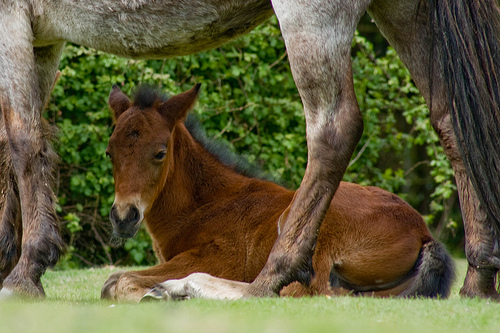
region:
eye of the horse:
[150, 145, 165, 160]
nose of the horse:
[110, 200, 146, 236]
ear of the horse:
[167, 90, 202, 121]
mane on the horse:
[187, 118, 245, 173]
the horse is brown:
[367, 223, 395, 256]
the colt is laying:
[82, 102, 426, 294]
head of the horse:
[93, 83, 182, 233]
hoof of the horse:
[242, 272, 305, 295]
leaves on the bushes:
[222, 85, 287, 132]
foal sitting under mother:
[81, 59, 446, 314]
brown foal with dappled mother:
[2, 0, 498, 332]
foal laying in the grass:
[66, 64, 463, 324]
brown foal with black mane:
[91, 75, 461, 319]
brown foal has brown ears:
[81, 70, 461, 327]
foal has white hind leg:
[134, 263, 268, 316]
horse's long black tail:
[419, 2, 496, 208]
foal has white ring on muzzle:
[98, 180, 153, 239]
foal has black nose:
[105, 200, 150, 242]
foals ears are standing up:
[99, 82, 213, 124]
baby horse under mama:
[73, 70, 444, 305]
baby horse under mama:
[37, 75, 459, 318]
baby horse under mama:
[76, 70, 453, 309]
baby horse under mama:
[10, 74, 442, 314]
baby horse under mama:
[97, 60, 460, 306]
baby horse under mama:
[57, 39, 456, 309]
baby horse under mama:
[33, 66, 450, 321]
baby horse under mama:
[72, 30, 460, 315]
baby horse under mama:
[64, 74, 460, 318]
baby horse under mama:
[10, 54, 455, 314]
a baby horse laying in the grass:
[100, 81, 455, 302]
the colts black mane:
[130, 82, 162, 112]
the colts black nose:
[109, 204, 141, 241]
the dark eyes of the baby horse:
[152, 145, 162, 160]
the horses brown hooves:
[1, 267, 46, 304]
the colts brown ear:
[157, 82, 201, 129]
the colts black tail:
[403, 240, 455, 302]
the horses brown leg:
[246, 0, 364, 295]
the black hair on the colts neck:
[188, 112, 258, 179]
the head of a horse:
[87, 82, 225, 244]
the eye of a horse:
[142, 142, 182, 171]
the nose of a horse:
[109, 196, 156, 238]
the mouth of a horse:
[103, 180, 176, 251]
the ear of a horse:
[142, 78, 221, 140]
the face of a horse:
[100, 99, 202, 234]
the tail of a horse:
[371, 205, 462, 294]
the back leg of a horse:
[227, 46, 416, 291]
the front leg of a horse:
[6, 25, 82, 291]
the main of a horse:
[119, 57, 312, 210]